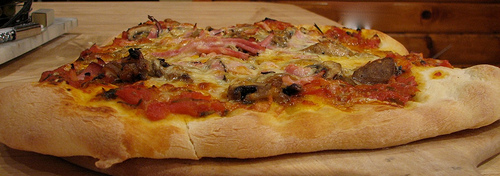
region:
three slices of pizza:
[46, 20, 473, 151]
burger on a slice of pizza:
[97, 45, 160, 76]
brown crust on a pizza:
[0, 69, 179, 162]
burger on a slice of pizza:
[350, 51, 405, 80]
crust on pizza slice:
[191, 110, 447, 158]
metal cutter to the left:
[1, 8, 86, 58]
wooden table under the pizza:
[407, 8, 477, 47]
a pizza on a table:
[32, 20, 452, 175]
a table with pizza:
[64, 12, 389, 168]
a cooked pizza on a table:
[87, 13, 493, 172]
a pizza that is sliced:
[60, 6, 415, 172]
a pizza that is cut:
[89, 10, 494, 155]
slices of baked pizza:
[57, 20, 426, 171]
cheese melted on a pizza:
[110, 8, 496, 168]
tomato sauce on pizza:
[96, 5, 496, 133]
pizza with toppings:
[72, 16, 403, 173]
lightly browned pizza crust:
[0, 64, 498, 161]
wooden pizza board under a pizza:
[74, 124, 499, 174]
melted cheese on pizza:
[179, 54, 389, 92]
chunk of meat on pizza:
[115, 43, 154, 85]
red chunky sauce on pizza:
[114, 79, 222, 126]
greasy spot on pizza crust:
[107, 114, 185, 159]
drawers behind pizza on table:
[314, 2, 498, 68]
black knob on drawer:
[422, 10, 432, 22]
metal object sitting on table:
[0, 2, 82, 68]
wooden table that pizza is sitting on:
[0, 2, 354, 86]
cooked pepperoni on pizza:
[114, 78, 234, 117]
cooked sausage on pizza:
[109, 46, 168, 76]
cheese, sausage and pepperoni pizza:
[226, 30, 456, 145]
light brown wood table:
[102, 0, 344, 35]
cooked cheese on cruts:
[99, 98, 189, 160]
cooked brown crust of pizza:
[408, 40, 490, 139]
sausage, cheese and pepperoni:
[51, 45, 187, 128]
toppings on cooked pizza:
[104, 22, 271, 97]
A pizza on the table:
[104, 26, 278, 91]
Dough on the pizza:
[282, 124, 397, 162]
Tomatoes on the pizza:
[132, 81, 191, 118]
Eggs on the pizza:
[188, 47, 261, 92]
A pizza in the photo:
[100, 20, 400, 140]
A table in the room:
[408, 17, 478, 59]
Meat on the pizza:
[104, 53, 156, 83]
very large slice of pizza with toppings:
[0, 19, 495, 166]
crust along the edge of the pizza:
[3, 65, 494, 162]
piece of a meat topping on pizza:
[349, 57, 394, 79]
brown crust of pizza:
[0, 66, 240, 158]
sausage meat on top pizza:
[346, 45, 396, 90]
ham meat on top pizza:
[42, 51, 107, 93]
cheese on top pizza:
[111, 71, 246, 122]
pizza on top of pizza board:
[5, 10, 495, 170]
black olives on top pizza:
[231, 72, 301, 108]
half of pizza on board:
[10, 12, 482, 159]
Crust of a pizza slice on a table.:
[3, 67, 499, 156]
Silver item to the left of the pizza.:
[1, 24, 45, 44]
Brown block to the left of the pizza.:
[30, 6, 56, 27]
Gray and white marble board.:
[1, 14, 76, 66]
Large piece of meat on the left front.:
[351, 55, 401, 86]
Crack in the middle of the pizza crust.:
[173, 115, 218, 162]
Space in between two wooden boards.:
[386, 25, 498, 38]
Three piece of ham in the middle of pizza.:
[197, 31, 274, 58]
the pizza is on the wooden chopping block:
[17, 10, 488, 166]